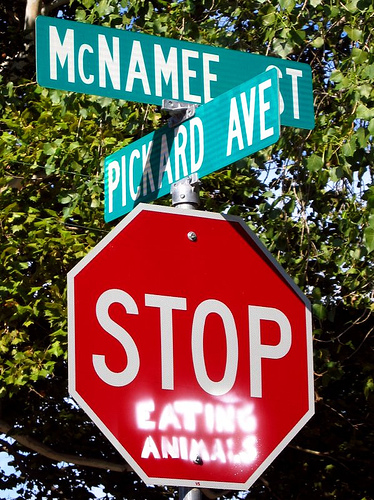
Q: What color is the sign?
A: Red.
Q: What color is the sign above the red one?
A: Green.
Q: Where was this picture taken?
A: The corner of Pickard Ave. and McNamee St.